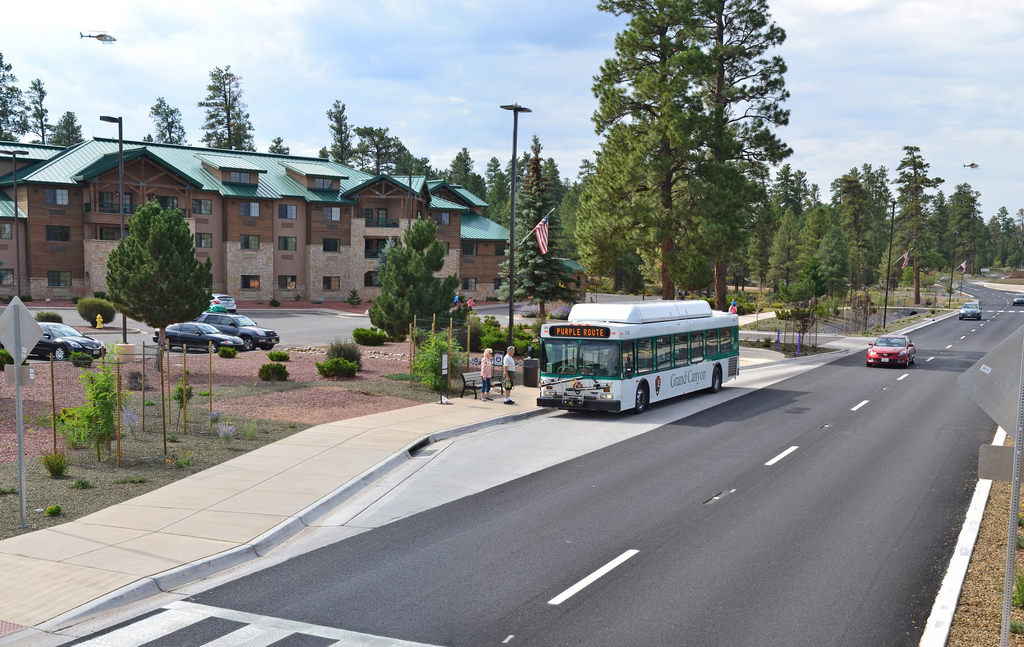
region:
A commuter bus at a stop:
[531, 288, 760, 415]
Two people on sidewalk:
[472, 344, 521, 401]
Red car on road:
[864, 328, 915, 370]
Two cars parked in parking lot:
[153, 310, 275, 367]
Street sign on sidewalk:
[0, 293, 49, 538]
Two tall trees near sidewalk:
[588, 0, 795, 302]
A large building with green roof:
[0, 132, 533, 313]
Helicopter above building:
[74, 26, 133, 49]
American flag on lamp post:
[517, 205, 557, 263]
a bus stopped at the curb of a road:
[523, 323, 729, 431]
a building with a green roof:
[108, 136, 440, 238]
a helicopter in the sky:
[65, 13, 139, 58]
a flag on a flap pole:
[512, 203, 557, 261]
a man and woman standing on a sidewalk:
[481, 343, 524, 407]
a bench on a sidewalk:
[456, 365, 489, 398]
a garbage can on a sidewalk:
[519, 354, 539, 390]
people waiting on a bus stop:
[460, 316, 560, 430]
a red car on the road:
[852, 304, 932, 384]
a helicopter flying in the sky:
[70, 15, 119, 64]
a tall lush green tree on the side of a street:
[554, 15, 799, 368]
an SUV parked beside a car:
[160, 302, 287, 347]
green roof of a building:
[11, 128, 492, 218]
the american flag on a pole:
[511, 203, 563, 260]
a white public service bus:
[539, 304, 742, 418]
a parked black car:
[156, 318, 237, 353]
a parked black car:
[32, 320, 105, 365]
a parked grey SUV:
[198, 311, 281, 350]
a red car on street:
[864, 336, 915, 368]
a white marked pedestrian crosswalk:
[57, 593, 446, 645]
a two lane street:
[65, 276, 1020, 641]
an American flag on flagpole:
[510, 206, 555, 261]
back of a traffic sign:
[4, 296, 44, 366]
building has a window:
[326, 209, 342, 223]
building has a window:
[273, 203, 292, 220]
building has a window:
[280, 239, 296, 252]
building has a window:
[244, 236, 261, 252]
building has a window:
[248, 200, 259, 220]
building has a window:
[324, 206, 337, 220]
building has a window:
[315, 239, 338, 252]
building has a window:
[277, 274, 296, 287]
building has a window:
[242, 271, 261, 288]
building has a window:
[238, 230, 257, 250]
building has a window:
[239, 199, 255, 218]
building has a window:
[283, 200, 294, 216]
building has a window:
[197, 198, 214, 211]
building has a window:
[225, 165, 249, 182]